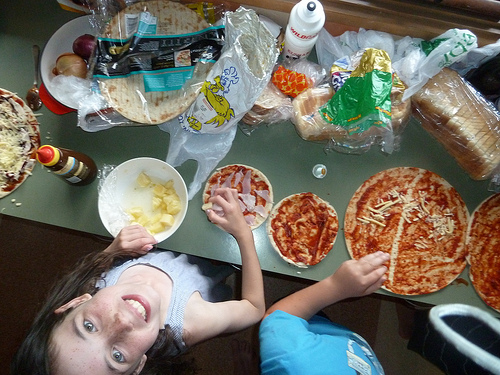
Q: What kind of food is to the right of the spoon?
A: The food is a tortilla.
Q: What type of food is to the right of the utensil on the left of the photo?
A: The food is a tortilla.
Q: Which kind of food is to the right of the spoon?
A: The food is a tortilla.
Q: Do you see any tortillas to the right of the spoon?
A: Yes, there is a tortilla to the right of the spoon.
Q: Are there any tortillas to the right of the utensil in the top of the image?
A: Yes, there is a tortilla to the right of the spoon.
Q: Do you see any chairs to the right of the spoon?
A: No, there is a tortilla to the right of the spoon.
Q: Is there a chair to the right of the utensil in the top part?
A: No, there is a tortilla to the right of the spoon.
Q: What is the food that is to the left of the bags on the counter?
A: The food is a tortilla.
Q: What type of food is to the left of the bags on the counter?
A: The food is a tortilla.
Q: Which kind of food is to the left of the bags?
A: The food is a tortilla.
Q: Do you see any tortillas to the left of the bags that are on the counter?
A: Yes, there is a tortilla to the left of the bags.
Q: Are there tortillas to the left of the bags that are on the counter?
A: Yes, there is a tortilla to the left of the bags.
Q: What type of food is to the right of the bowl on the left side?
A: The food is a tortilla.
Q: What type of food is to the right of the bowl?
A: The food is a tortilla.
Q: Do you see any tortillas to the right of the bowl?
A: Yes, there is a tortilla to the right of the bowl.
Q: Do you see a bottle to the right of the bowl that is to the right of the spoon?
A: No, there is a tortilla to the right of the bowl.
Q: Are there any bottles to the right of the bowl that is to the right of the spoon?
A: No, there is a tortilla to the right of the bowl.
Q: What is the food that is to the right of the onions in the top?
A: The food is a tortilla.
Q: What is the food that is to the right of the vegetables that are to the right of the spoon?
A: The food is a tortilla.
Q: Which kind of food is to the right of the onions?
A: The food is a tortilla.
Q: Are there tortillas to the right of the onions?
A: Yes, there is a tortilla to the right of the onions.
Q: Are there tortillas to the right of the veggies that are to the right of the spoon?
A: Yes, there is a tortilla to the right of the onions.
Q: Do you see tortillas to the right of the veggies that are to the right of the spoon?
A: Yes, there is a tortilla to the right of the onions.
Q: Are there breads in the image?
A: Yes, there is a bread.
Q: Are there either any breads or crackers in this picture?
A: Yes, there is a bread.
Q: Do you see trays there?
A: No, there are no trays.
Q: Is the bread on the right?
A: Yes, the bread is on the right of the image.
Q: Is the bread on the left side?
A: No, the bread is on the right of the image.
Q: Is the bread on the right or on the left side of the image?
A: The bread is on the right of the image.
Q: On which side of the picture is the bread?
A: The bread is on the right of the image.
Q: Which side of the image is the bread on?
A: The bread is on the right of the image.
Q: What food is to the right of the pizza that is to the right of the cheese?
A: The food is a bread.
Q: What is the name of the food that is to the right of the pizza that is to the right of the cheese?
A: The food is a bread.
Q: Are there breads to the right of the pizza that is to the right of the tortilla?
A: Yes, there is a bread to the right of the pizza.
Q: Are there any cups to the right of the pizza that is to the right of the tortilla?
A: No, there is a bread to the right of the pizza.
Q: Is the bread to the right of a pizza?
A: Yes, the bread is to the right of a pizza.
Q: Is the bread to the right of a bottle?
A: No, the bread is to the right of a pizza.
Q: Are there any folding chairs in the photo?
A: No, there are no folding chairs.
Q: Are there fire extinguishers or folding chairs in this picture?
A: No, there are no folding chairs or fire extinguishers.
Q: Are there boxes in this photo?
A: No, there are no boxes.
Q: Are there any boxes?
A: No, there are no boxes.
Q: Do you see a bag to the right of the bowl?
A: Yes, there are bags to the right of the bowl.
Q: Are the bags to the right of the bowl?
A: Yes, the bags are to the right of the bowl.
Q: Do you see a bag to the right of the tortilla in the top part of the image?
A: Yes, there are bags to the right of the tortilla.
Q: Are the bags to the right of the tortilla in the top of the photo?
A: Yes, the bags are to the right of the tortilla.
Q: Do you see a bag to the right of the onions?
A: Yes, there are bags to the right of the onions.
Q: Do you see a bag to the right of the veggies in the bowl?
A: Yes, there are bags to the right of the onions.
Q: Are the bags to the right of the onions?
A: Yes, the bags are to the right of the onions.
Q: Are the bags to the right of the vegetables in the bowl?
A: Yes, the bags are to the right of the onions.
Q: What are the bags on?
A: The bags are on the counter.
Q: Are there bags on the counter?
A: Yes, there are bags on the counter.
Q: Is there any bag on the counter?
A: Yes, there are bags on the counter.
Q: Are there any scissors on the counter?
A: No, there are bags on the counter.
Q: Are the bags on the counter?
A: Yes, the bags are on the counter.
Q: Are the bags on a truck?
A: No, the bags are on the counter.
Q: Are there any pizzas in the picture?
A: Yes, there is a pizza.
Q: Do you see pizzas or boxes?
A: Yes, there is a pizza.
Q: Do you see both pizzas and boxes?
A: No, there is a pizza but no boxes.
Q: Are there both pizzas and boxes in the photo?
A: No, there is a pizza but no boxes.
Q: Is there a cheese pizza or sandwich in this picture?
A: Yes, there is a cheese pizza.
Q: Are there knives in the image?
A: No, there are no knives.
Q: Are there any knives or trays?
A: No, there are no knives or trays.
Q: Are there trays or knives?
A: No, there are no knives or trays.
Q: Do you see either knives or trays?
A: No, there are no knives or trays.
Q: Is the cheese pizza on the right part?
A: Yes, the pizza is on the right of the image.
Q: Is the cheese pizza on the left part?
A: No, the pizza is on the right of the image.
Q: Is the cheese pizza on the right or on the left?
A: The pizza is on the right of the image.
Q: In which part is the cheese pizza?
A: The pizza is on the right of the image.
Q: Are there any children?
A: Yes, there is a child.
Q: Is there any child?
A: Yes, there is a child.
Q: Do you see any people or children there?
A: Yes, there is a child.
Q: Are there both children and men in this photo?
A: No, there is a child but no men.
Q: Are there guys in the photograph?
A: No, there are no guys.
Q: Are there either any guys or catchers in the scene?
A: No, there are no guys or catchers.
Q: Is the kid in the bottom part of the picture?
A: Yes, the kid is in the bottom of the image.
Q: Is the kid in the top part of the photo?
A: No, the kid is in the bottom of the image.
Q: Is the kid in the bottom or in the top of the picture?
A: The kid is in the bottom of the image.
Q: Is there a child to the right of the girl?
A: Yes, there is a child to the right of the girl.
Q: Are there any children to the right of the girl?
A: Yes, there is a child to the right of the girl.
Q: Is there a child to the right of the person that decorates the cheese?
A: Yes, there is a child to the right of the girl.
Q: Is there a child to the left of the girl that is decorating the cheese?
A: No, the child is to the right of the girl.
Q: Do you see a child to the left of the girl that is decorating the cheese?
A: No, the child is to the right of the girl.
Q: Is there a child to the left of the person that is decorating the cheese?
A: No, the child is to the right of the girl.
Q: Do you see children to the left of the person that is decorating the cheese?
A: No, the child is to the right of the girl.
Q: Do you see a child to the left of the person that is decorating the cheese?
A: No, the child is to the right of the girl.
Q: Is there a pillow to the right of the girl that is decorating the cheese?
A: No, there is a child to the right of the girl.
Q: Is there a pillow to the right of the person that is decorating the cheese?
A: No, there is a child to the right of the girl.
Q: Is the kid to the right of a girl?
A: Yes, the kid is to the right of a girl.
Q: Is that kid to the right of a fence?
A: No, the kid is to the right of a girl.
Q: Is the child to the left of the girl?
A: No, the child is to the right of the girl.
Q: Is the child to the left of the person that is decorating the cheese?
A: No, the child is to the right of the girl.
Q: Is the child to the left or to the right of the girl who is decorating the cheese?
A: The child is to the right of the girl.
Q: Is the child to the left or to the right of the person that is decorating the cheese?
A: The child is to the right of the girl.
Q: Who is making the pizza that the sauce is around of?
A: The child is making the pizza.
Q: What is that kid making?
A: The kid is making the pizza.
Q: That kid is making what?
A: The kid is making the pizza.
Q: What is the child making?
A: The kid is making the pizza.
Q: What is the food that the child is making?
A: The food is a pizza.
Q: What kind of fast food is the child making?
A: The child is making the pizza.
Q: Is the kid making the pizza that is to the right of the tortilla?
A: Yes, the kid is making the pizza.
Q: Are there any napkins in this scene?
A: No, there are no napkins.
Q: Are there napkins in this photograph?
A: No, there are no napkins.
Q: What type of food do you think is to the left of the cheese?
A: The food is a tortilla.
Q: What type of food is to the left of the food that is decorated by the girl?
A: The food is a tortilla.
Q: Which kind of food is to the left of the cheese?
A: The food is a tortilla.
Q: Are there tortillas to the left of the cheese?
A: Yes, there is a tortilla to the left of the cheese.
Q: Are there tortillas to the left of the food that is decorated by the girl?
A: Yes, there is a tortilla to the left of the cheese.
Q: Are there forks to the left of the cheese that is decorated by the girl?
A: No, there is a tortilla to the left of the cheese.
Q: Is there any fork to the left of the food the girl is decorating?
A: No, there is a tortilla to the left of the cheese.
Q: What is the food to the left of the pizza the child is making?
A: The food is a tortilla.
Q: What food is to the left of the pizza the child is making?
A: The food is a tortilla.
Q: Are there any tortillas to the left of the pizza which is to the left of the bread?
A: Yes, there is a tortilla to the left of the pizza.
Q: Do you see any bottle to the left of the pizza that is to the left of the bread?
A: No, there is a tortilla to the left of the pizza.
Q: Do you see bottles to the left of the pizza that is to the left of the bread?
A: No, there is a tortilla to the left of the pizza.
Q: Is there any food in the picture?
A: Yes, there is food.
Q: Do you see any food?
A: Yes, there is food.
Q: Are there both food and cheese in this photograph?
A: Yes, there are both food and cheese.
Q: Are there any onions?
A: Yes, there are onions.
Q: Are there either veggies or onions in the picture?
A: Yes, there are onions.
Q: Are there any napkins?
A: No, there are no napkins.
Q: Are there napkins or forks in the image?
A: No, there are no napkins or forks.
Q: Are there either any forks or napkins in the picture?
A: No, there are no napkins or forks.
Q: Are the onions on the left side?
A: Yes, the onions are on the left of the image.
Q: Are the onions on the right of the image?
A: No, the onions are on the left of the image.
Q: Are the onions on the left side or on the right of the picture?
A: The onions are on the left of the image.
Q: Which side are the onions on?
A: The onions are on the left of the image.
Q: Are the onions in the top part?
A: Yes, the onions are in the top of the image.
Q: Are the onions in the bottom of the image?
A: No, the onions are in the top of the image.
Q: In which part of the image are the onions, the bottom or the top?
A: The onions are in the top of the image.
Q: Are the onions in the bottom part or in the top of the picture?
A: The onions are in the top of the image.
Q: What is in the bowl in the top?
A: The onions are in the bowl.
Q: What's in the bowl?
A: The onions are in the bowl.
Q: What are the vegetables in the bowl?
A: The vegetables are onions.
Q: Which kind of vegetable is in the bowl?
A: The vegetables are onions.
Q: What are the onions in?
A: The onions are in the bowl.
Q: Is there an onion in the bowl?
A: Yes, there are onions in the bowl.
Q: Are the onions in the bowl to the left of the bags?
A: Yes, the onions are in the bowl.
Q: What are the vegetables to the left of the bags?
A: The vegetables are onions.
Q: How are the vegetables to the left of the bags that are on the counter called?
A: The vegetables are onions.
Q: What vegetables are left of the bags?
A: The vegetables are onions.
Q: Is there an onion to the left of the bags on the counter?
A: Yes, there are onions to the left of the bags.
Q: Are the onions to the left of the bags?
A: Yes, the onions are to the left of the bags.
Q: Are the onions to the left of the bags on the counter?
A: Yes, the onions are to the left of the bags.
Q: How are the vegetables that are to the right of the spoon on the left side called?
A: The vegetables are onions.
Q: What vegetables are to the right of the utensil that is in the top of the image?
A: The vegetables are onions.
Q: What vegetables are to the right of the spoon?
A: The vegetables are onions.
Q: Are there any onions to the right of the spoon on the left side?
A: Yes, there are onions to the right of the spoon.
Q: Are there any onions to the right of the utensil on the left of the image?
A: Yes, there are onions to the right of the spoon.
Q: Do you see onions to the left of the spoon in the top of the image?
A: No, the onions are to the right of the spoon.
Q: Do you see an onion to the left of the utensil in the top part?
A: No, the onions are to the right of the spoon.